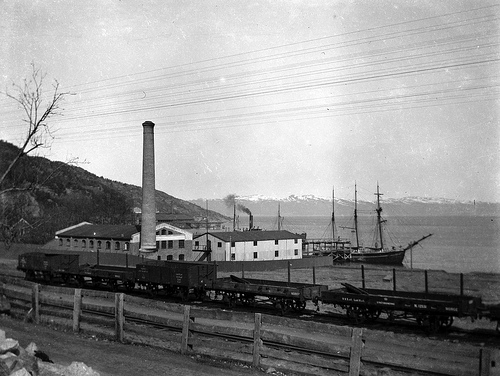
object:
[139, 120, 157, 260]
smokestack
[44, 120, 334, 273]
factory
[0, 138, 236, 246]
hillside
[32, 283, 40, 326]
post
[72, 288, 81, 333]
post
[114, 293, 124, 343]
post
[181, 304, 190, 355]
post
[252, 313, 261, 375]
post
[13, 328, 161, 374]
dirt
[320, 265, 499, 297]
dirt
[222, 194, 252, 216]
smoke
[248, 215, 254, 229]
smoke stack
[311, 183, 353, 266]
boat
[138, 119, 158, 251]
building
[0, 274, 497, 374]
wooden fence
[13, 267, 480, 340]
tracks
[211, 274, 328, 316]
cars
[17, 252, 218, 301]
caboose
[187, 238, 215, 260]
steps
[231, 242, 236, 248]
windows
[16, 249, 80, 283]
car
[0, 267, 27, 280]
rail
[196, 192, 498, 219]
mountains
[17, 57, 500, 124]
power lines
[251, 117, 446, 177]
clouds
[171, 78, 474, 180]
gray sky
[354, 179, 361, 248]
mast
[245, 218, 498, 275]
ocean water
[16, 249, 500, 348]
train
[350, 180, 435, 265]
boat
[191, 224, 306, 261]
building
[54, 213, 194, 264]
building